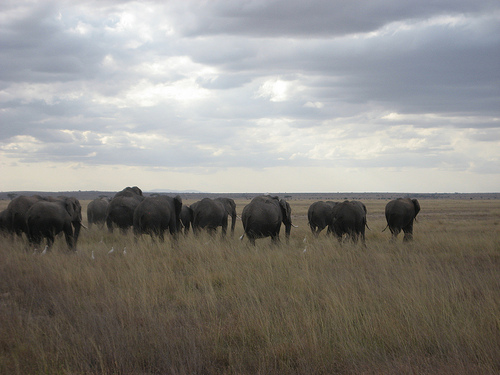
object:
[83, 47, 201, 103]
clouds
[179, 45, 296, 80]
sky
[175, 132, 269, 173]
sky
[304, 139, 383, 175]
clouds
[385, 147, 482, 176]
sky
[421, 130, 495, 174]
clouds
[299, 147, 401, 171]
sky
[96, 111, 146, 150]
clouds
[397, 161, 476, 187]
sky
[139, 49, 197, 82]
clouds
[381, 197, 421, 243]
cows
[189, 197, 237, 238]
elephants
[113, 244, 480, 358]
grass field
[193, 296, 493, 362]
grass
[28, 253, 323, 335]
grass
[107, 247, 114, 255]
birds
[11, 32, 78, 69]
sky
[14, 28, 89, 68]
clouds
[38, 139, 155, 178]
sky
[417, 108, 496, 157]
clouds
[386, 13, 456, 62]
clouds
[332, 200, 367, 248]
cows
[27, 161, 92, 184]
sky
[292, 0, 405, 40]
clouds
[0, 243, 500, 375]
field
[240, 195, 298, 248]
elephants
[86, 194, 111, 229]
elephants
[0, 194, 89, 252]
elephants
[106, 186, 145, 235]
elephants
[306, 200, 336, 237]
elephants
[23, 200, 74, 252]
elephants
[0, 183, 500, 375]
wildlife park